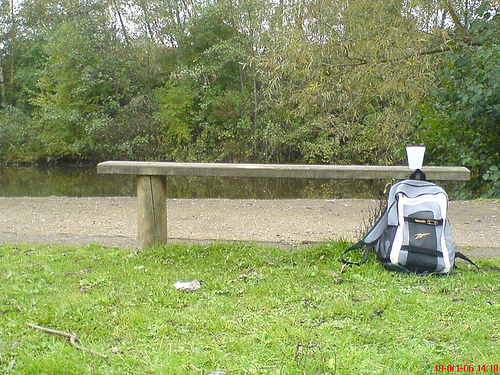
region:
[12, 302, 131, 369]
Stick laying on the green grass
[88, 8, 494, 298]
Park bench with no one there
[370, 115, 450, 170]
Drink on the bench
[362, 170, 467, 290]
Backpack leaning against the bench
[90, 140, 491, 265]
Wooden park bench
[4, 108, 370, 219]
Lake behind the bench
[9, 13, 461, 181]
Lots of green trees and shrubbery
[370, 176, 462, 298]
Gray and white backpack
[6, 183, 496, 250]
Dirt walking path behind the bench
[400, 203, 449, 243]
Brand logo on the backpack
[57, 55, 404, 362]
picture taken outdoors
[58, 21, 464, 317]
picture taken during the day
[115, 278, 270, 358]
the grass is brigt green and brown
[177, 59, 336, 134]
the trees are green and yellow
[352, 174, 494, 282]
a backpack is on the ground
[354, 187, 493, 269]
the backpack is against the bench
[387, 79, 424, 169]
a cup is on the bench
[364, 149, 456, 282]
the backpack is blue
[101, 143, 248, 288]
the bench is made of wood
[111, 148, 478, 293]
the bench has two legs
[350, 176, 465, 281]
BACKPACK SITTING NEXT TO BENCH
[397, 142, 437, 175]
STYROFOAM CUP ON BENCH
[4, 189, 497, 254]
DIRT AND GRAVEL PATH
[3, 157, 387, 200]
SMALL POND NEXT TO PARK BENCH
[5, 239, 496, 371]
GRASSY REST AREA IN PARK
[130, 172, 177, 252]
SHORT WOODEN SUPPORT POST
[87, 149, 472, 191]
LONG STRAIGHT BOARD USED AS SEAT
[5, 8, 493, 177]
TREES AND BUSHES AROUND WATER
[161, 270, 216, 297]
TRASH LITTERING GRASS AREA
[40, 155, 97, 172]
RAISED SHORELINE NEAR BODY OF WATER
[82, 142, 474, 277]
cement and wood bench in park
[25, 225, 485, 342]
grass in front of bench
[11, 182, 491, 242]
gravel path in back of bench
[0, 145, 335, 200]
pond with greenish water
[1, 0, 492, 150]
trees along the edge of the pond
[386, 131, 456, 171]
white cup on top of the bench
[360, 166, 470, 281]
backpack resting on bench suppot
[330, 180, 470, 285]
blue and white backpack with black straps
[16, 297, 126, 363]
angled twig on grass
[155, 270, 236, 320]
white litter on top of grass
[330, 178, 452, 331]
blue gray and white back pack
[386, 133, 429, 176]
white cup on wood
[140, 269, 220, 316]
litter on the grass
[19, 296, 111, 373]
stick in the grass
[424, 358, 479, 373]
a date written in red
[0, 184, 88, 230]
gravel beside the water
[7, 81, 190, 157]
a group of trees and bushes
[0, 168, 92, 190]
reflection on the water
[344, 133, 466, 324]
white cup beside back pack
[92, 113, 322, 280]
bench by the water